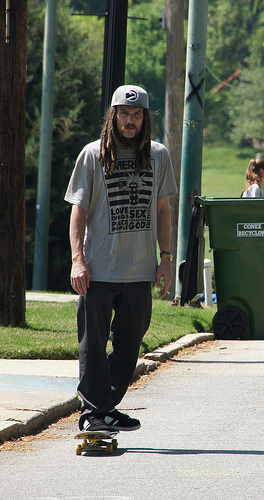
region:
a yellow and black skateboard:
[71, 427, 129, 457]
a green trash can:
[197, 198, 263, 341]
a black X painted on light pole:
[179, 72, 208, 118]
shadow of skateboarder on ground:
[120, 440, 263, 460]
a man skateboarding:
[39, 82, 188, 456]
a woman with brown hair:
[239, 155, 263, 204]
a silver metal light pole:
[32, 3, 58, 297]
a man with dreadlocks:
[83, 89, 164, 179]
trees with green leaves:
[55, 29, 98, 148]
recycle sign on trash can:
[236, 222, 262, 236]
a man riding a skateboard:
[64, 84, 172, 429]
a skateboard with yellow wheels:
[73, 429, 119, 453]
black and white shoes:
[79, 409, 140, 432]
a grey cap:
[110, 84, 149, 109]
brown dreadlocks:
[98, 106, 151, 175]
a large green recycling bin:
[181, 190, 262, 337]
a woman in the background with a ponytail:
[241, 158, 263, 197]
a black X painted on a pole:
[186, 71, 204, 107]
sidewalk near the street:
[0, 357, 155, 452]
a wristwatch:
[159, 251, 173, 260]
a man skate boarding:
[57, 70, 182, 455]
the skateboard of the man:
[72, 420, 162, 482]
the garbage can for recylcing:
[195, 177, 262, 347]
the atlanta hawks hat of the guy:
[108, 77, 160, 111]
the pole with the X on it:
[166, 51, 230, 133]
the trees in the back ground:
[220, 28, 260, 142]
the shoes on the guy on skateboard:
[70, 408, 149, 433]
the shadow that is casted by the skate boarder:
[142, 431, 255, 480]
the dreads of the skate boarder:
[84, 112, 117, 175]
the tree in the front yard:
[0, 18, 40, 331]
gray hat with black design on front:
[110, 81, 160, 115]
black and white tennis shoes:
[82, 398, 143, 437]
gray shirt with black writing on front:
[67, 131, 192, 289]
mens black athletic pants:
[64, 267, 157, 409]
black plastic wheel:
[199, 298, 262, 353]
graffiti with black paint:
[175, 29, 215, 137]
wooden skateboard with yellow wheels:
[68, 412, 126, 474]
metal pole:
[28, 3, 60, 287]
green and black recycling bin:
[185, 179, 260, 380]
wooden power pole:
[1, 9, 31, 281]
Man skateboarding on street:
[62, 82, 173, 453]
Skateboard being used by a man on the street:
[70, 421, 117, 453]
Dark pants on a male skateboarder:
[72, 280, 151, 403]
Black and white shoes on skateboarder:
[77, 404, 139, 433]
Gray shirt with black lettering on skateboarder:
[66, 135, 179, 279]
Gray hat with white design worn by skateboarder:
[109, 82, 148, 107]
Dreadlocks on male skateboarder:
[95, 102, 151, 173]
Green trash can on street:
[176, 192, 260, 339]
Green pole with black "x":
[171, 1, 206, 300]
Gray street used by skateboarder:
[0, 337, 263, 498]